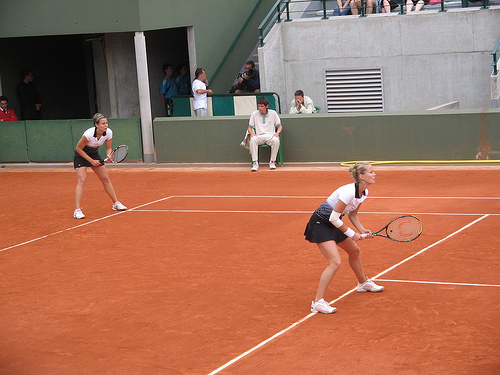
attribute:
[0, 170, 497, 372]
court — red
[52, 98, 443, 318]
women — playing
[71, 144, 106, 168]
skirt — dark blue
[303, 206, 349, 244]
skirt — dark blue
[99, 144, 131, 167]
racket — black, white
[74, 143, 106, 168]
skirt — black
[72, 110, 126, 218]
woman — brunette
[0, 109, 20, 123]
coat — red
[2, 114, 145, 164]
wall — green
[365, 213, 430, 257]
racket — tennis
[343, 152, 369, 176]
hair — blonde